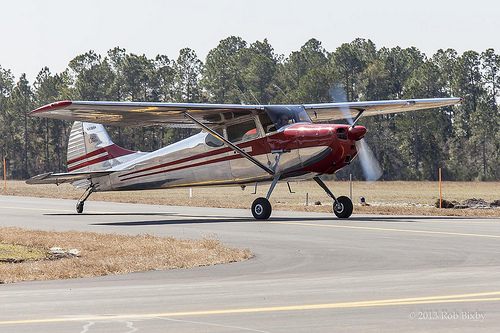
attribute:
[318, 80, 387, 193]
propeller — metal, spinning, in motion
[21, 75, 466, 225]
plane — old fashioned, taking off, small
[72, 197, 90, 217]
tire — small, black, tiny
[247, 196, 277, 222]
tire — black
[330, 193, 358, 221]
tire — black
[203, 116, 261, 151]
window — small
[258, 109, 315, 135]
window — clear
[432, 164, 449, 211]
post — orange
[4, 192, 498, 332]
runway — small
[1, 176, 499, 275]
grass — brown, parched, dead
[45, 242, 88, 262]
stone — white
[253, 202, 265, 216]
trim — white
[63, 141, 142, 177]
stripe — red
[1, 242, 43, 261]
grass — green, small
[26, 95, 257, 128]
wing — small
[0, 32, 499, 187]
trees — green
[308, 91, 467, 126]
wing — small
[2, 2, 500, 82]
sky — light, clear